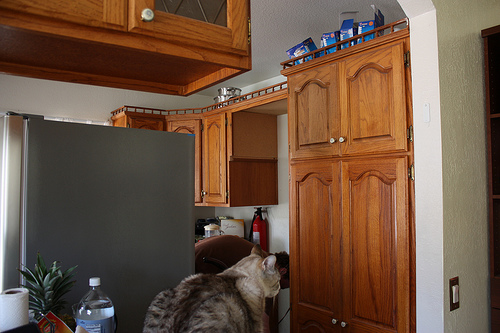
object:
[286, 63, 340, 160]
door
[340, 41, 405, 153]
door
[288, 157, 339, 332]
door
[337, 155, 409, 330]
door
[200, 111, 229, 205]
door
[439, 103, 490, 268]
white wall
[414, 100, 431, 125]
light switch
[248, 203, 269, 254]
extinguisher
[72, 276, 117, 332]
bottle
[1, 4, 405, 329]
kitchen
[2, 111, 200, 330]
refrigerator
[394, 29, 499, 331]
wall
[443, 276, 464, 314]
receptical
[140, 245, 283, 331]
cat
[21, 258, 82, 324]
plant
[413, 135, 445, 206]
ground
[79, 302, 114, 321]
water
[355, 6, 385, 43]
box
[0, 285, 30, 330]
paper towels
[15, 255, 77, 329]
pineapple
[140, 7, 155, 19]
knob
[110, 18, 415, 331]
cabinet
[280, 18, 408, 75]
top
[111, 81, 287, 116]
top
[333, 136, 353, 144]
knob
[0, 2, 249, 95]
cupboard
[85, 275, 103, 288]
top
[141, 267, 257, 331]
body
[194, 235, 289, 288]
person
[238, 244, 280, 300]
head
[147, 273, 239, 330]
back fur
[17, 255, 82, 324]
fronds